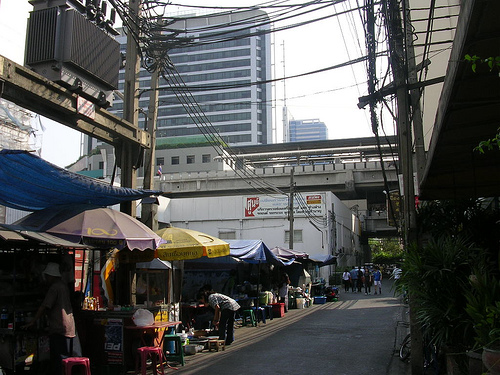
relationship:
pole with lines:
[107, 3, 159, 230] [106, 1, 402, 71]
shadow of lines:
[182, 298, 362, 375] [197, 295, 364, 373]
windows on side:
[216, 230, 305, 251] [172, 192, 327, 300]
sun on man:
[59, 304, 80, 337] [33, 265, 80, 352]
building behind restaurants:
[105, 8, 284, 169] [0, 200, 83, 375]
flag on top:
[157, 164, 163, 176] [153, 190, 338, 196]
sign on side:
[246, 190, 326, 221] [172, 192, 327, 300]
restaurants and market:
[36, 204, 317, 353] [6, 157, 327, 374]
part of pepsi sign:
[3, 305, 53, 342] [6, 321, 15, 328]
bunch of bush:
[393, 146, 500, 374] [390, 140, 497, 373]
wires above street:
[129, 1, 441, 96] [7, 103, 429, 373]